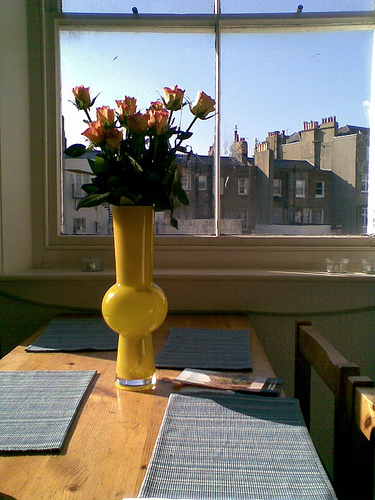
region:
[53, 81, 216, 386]
vase with flowers on table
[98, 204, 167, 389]
vase is yellow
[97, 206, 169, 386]
vase is cylindrical with round bulge in the middle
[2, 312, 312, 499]
table is wooden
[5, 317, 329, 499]
four placemats on table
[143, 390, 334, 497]
blue placemat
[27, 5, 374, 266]
large window behind table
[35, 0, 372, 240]
window has at least four panes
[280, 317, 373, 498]
two wooden chairs next to table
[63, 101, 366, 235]
several buildings seen out of window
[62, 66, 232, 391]
yellow vase with flowers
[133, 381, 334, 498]
blue striped placemat on table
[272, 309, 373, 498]
wooden chairs by table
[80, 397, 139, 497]
wooden table where vase is on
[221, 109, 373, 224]
buildings in the distance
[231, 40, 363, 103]
blue sky in the distance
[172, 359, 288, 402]
pamphlet on the table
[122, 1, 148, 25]
window lock above frame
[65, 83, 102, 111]
pink long stem rose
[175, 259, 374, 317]
cream colored window sill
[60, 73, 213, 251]
roses in a vase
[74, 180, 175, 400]
bright yellow modern vase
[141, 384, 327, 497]
gray woven fabric place mat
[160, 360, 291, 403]
brochures on table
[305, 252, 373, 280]
small glass candle holders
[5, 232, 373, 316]
wood painted window sill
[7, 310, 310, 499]
wood dining table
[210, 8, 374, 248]
buildings seen through a window pane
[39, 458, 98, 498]
knot in wood surface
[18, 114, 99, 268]
painted molding around window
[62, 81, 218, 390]
a bouquet in a yellow vase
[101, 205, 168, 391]
a tall yellow vase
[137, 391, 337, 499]
a blue placemat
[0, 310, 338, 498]
a wooden breakfast table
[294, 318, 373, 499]
a pair of wooden chairs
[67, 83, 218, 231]
a boquet of roses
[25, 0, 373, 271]
the view out the window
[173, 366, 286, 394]
a pamphlet on the table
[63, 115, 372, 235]
brick buildings out the window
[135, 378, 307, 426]
the vase's shadow on the table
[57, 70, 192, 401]
large vase filled with flowers.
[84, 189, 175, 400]
Large yellow glass vase.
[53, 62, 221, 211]
bouquet of red and pink roses.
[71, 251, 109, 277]
Small glass votive with a candle in it.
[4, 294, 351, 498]
Wood kitchen table with chairs.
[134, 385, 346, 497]
Blue placemat.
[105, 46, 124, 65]
Bird flying in the sky.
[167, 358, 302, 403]
Brochure sitting on the table.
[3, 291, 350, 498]
Table with four placemats.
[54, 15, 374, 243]
View of neighboring buildings from the window.